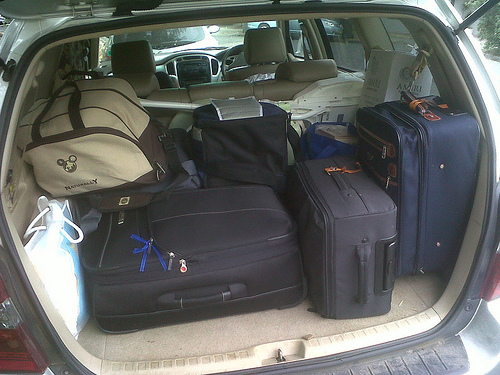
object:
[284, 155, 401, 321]
suitcase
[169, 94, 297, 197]
suitcase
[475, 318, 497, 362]
floor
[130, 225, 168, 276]
ribbon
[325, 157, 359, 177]
ribbon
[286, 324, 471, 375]
rubber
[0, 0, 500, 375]
car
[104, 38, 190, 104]
driver seat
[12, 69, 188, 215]
backpack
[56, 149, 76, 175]
design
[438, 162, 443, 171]
rivet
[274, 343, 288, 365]
rear/door latch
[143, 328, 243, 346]
carpet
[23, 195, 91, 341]
white bag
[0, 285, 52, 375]
red/tail light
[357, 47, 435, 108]
white/cardboard box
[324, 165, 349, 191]
black handle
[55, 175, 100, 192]
text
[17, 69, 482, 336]
luggage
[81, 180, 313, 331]
luggage piece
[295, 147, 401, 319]
luggage piece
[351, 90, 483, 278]
luggage piece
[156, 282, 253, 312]
handle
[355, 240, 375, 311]
handle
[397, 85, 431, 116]
handle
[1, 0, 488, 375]
cargo area